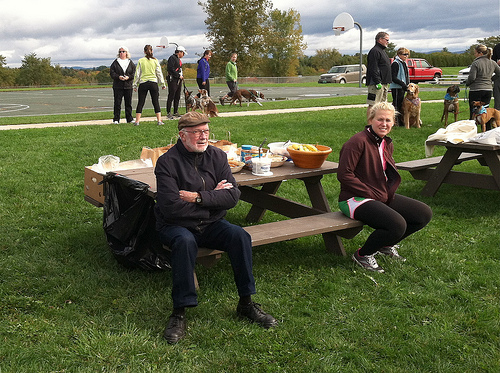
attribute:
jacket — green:
[225, 56, 240, 81]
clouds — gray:
[108, 11, 193, 36]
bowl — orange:
[293, 155, 326, 166]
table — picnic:
[129, 165, 149, 180]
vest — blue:
[395, 60, 410, 90]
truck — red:
[405, 57, 442, 84]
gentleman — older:
[104, 87, 267, 332]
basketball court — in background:
[0, 12, 372, 119]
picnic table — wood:
[100, 147, 366, 268]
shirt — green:
[223, 61, 240, 84]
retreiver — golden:
[398, 80, 427, 132]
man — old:
[145, 99, 282, 334]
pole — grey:
[349, 21, 369, 75]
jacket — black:
[334, 130, 407, 211]